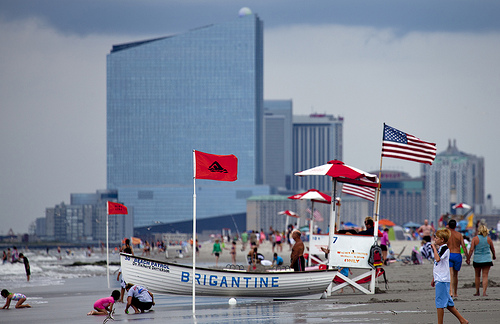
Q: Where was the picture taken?
A: It was taken at the city.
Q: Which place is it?
A: It is a city.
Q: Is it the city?
A: Yes, it is the city.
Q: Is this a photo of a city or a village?
A: It is showing a city.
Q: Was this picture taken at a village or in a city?
A: It was taken at a city.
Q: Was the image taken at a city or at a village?
A: It was taken at a city.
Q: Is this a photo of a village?
A: No, the picture is showing a city.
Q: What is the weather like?
A: It is cloudy.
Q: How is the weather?
A: It is cloudy.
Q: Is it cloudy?
A: Yes, it is cloudy.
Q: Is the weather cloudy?
A: Yes, it is cloudy.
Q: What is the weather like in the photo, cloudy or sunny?
A: It is cloudy.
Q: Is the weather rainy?
A: No, it is cloudy.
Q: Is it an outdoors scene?
A: Yes, it is outdoors.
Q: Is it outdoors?
A: Yes, it is outdoors.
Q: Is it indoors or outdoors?
A: It is outdoors.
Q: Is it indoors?
A: No, it is outdoors.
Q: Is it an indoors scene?
A: No, it is outdoors.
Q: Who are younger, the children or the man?
A: The children are younger than the man.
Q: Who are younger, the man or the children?
A: The children are younger than the man.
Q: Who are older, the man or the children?
A: The man are older than the children.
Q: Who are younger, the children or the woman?
A: The children are younger than the woman.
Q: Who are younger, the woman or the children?
A: The children are younger than the woman.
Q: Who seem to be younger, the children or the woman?
A: The children are younger than the woman.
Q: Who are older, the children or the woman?
A: The woman are older than the children.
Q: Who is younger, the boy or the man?
A: The boy is younger than the man.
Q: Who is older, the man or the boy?
A: The man is older than the boy.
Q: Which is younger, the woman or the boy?
A: The boy is younger than the woman.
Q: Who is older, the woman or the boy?
A: The woman is older than the boy.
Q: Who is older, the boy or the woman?
A: The woman is older than the boy.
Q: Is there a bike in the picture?
A: No, there are no bikes.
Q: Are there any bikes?
A: No, there are no bikes.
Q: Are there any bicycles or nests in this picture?
A: No, there are no bicycles or nests.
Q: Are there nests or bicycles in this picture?
A: No, there are no bicycles or nests.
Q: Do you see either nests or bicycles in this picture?
A: No, there are no bicycles or nests.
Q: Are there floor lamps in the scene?
A: No, there are no floor lamps.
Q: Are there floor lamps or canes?
A: No, there are no floor lamps or canes.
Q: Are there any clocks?
A: No, there are no clocks.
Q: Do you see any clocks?
A: No, there are no clocks.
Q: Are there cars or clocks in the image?
A: No, there are no clocks or cars.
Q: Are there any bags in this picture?
A: No, there are no bags.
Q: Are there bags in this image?
A: No, there are no bags.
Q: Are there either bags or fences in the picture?
A: No, there are no bags or fences.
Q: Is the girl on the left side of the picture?
A: Yes, the girl is on the left of the image.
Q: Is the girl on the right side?
A: No, the girl is on the left of the image.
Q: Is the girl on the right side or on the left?
A: The girl is on the left of the image.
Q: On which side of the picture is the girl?
A: The girl is on the left of the image.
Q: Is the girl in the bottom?
A: Yes, the girl is in the bottom of the image.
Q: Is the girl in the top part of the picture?
A: No, the girl is in the bottom of the image.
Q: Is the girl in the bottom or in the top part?
A: The girl is in the bottom of the image.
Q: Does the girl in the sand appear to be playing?
A: Yes, the girl is playing.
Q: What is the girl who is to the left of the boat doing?
A: The girl is playing.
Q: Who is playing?
A: The girl is playing.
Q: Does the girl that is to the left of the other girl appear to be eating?
A: No, the girl is playing.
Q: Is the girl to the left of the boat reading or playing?
A: The girl is playing.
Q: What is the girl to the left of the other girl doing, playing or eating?
A: The girl is playing.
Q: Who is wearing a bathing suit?
A: The girl is wearing a bathing suit.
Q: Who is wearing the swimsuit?
A: The girl is wearing a bathing suit.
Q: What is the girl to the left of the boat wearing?
A: The girl is wearing a bathing suit.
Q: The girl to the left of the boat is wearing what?
A: The girl is wearing a bathing suit.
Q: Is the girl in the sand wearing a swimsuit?
A: Yes, the girl is wearing a swimsuit.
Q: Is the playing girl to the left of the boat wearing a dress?
A: No, the girl is wearing a swimsuit.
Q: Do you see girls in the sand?
A: Yes, there is a girl in the sand.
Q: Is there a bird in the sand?
A: No, there is a girl in the sand.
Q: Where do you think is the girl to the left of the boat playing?
A: The girl is playing on the sand.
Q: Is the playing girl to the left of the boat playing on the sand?
A: Yes, the girl is playing on the sand.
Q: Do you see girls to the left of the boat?
A: Yes, there is a girl to the left of the boat.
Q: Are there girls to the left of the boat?
A: Yes, there is a girl to the left of the boat.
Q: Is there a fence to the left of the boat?
A: No, there is a girl to the left of the boat.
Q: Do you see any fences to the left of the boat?
A: No, there is a girl to the left of the boat.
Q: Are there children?
A: Yes, there are children.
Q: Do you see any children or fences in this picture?
A: Yes, there are children.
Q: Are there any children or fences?
A: Yes, there are children.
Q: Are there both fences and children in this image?
A: No, there are children but no fences.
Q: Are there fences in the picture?
A: No, there are no fences.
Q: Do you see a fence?
A: No, there are no fences.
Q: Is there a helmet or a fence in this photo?
A: No, there are no fences or helmets.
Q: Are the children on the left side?
A: Yes, the children are on the left of the image.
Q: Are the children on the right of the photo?
A: No, the children are on the left of the image.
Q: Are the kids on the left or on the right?
A: The kids are on the left of the image.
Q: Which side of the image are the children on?
A: The children are on the left of the image.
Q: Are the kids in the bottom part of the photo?
A: Yes, the kids are in the bottom of the image.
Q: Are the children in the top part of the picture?
A: No, the children are in the bottom of the image.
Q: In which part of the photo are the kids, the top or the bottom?
A: The kids are in the bottom of the image.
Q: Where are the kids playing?
A: The kids are playing on the sand.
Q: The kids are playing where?
A: The kids are playing on the sand.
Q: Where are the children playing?
A: The kids are playing on the sand.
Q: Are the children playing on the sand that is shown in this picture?
A: Yes, the children are playing on the sand.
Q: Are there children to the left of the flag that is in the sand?
A: Yes, there are children to the left of the flag.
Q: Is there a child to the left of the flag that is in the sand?
A: Yes, there are children to the left of the flag.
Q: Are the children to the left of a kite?
A: No, the children are to the left of the flag.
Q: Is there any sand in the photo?
A: Yes, there is sand.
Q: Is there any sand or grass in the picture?
A: Yes, there is sand.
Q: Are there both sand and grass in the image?
A: No, there is sand but no grass.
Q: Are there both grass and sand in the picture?
A: No, there is sand but no grass.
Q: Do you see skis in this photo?
A: No, there are no skis.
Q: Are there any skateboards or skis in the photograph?
A: No, there are no skis or skateboards.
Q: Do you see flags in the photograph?
A: Yes, there is a flag.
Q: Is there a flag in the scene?
A: Yes, there is a flag.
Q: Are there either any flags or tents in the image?
A: Yes, there is a flag.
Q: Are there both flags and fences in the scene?
A: No, there is a flag but no fences.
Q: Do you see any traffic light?
A: No, there are no traffic lights.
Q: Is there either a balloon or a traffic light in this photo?
A: No, there are no traffic lights or balloons.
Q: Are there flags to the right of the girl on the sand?
A: Yes, there is a flag to the right of the girl.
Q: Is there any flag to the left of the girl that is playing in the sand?
A: No, the flag is to the right of the girl.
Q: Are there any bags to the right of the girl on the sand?
A: No, there is a flag to the right of the girl.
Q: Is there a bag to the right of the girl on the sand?
A: No, there is a flag to the right of the girl.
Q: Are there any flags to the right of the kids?
A: Yes, there is a flag to the right of the kids.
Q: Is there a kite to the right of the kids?
A: No, there is a flag to the right of the kids.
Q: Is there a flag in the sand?
A: Yes, there is a flag in the sand.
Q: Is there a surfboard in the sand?
A: No, there is a flag in the sand.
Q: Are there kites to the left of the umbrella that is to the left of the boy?
A: No, there is a flag to the left of the umbrella.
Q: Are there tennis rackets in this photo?
A: No, there are no tennis rackets.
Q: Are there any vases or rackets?
A: No, there are no rackets or vases.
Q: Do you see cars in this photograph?
A: No, there are no cars.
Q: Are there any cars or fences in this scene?
A: No, there are no cars or fences.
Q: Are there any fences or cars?
A: No, there are no cars or fences.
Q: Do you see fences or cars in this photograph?
A: No, there are no cars or fences.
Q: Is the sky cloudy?
A: Yes, the sky is cloudy.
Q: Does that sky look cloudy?
A: Yes, the sky is cloudy.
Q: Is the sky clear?
A: No, the sky is cloudy.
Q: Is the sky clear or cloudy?
A: The sky is cloudy.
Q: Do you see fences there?
A: No, there are no fences.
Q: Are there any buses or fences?
A: No, there are no fences or buses.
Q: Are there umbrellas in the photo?
A: Yes, there is an umbrella.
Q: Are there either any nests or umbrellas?
A: Yes, there is an umbrella.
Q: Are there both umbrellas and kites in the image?
A: No, there is an umbrella but no kites.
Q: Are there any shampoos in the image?
A: No, there are no shampoos.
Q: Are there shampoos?
A: No, there are no shampoos.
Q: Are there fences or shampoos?
A: No, there are no shampoos or fences.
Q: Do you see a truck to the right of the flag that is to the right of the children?
A: No, there is an umbrella to the right of the flag.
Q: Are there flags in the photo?
A: Yes, there is a flag.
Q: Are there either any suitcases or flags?
A: Yes, there is a flag.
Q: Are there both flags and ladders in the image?
A: No, there is a flag but no ladders.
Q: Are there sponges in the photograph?
A: No, there are no sponges.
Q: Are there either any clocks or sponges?
A: No, there are no sponges or clocks.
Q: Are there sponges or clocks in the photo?
A: No, there are no sponges or clocks.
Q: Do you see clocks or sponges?
A: No, there are no sponges or clocks.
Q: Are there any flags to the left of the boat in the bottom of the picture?
A: Yes, there is a flag to the left of the boat.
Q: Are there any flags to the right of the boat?
A: No, the flag is to the left of the boat.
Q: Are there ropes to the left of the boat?
A: No, there is a flag to the left of the boat.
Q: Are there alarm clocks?
A: No, there are no alarm clocks.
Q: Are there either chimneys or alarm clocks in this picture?
A: No, there are no alarm clocks or chimneys.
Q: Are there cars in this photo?
A: No, there are no cars.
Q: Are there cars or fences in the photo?
A: No, there are no cars or fences.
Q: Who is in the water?
A: The people are in the water.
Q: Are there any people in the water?
A: Yes, there are people in the water.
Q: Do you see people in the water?
A: Yes, there are people in the water.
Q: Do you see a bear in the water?
A: No, there are people in the water.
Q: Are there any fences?
A: No, there are no fences.